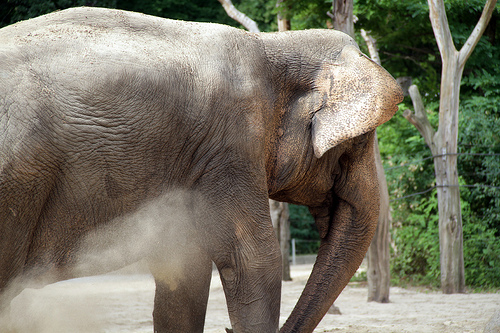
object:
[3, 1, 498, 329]
enclosure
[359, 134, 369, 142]
eye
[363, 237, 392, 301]
leg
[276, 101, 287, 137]
warts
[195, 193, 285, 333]
leg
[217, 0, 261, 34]
bark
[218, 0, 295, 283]
trees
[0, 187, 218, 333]
dust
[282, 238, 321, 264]
fence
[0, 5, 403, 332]
elephant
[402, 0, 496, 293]
tree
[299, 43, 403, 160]
ear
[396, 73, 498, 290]
bushes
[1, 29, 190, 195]
wrinkled skin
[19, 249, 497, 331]
ground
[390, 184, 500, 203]
rope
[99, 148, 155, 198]
spot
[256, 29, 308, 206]
elephant neck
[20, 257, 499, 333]
dirt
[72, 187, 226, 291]
cloud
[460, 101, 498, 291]
bush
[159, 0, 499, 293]
leaves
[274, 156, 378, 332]
elephant's trunk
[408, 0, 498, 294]
bark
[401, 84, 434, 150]
branch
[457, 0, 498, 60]
branch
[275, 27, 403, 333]
head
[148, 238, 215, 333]
leg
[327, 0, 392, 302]
tree